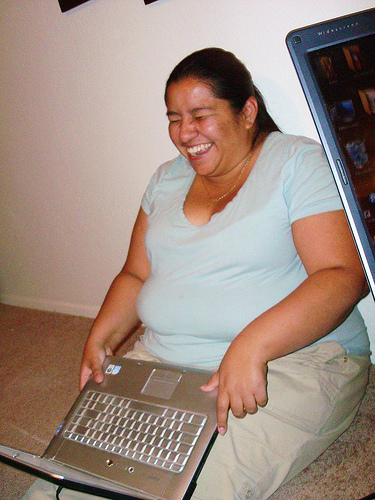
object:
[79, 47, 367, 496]
woman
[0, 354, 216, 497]
laptop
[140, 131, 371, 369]
shirt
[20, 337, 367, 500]
pants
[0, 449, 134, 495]
floor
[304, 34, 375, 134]
corner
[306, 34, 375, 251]
screen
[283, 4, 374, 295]
laptop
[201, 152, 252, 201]
necklace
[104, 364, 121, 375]
stickers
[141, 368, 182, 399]
touchpad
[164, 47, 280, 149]
hair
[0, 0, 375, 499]
picture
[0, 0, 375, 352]
wall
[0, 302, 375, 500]
chair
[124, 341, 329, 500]
lap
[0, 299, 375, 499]
carpet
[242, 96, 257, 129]
ear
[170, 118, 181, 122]
eye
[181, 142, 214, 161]
mouth